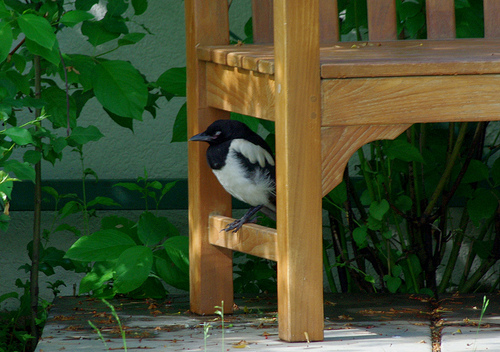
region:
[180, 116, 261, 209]
this is a bird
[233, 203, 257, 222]
this is the leg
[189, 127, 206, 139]
this is the beak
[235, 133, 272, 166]
this is the wing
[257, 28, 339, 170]
this is a bench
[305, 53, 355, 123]
the bench is brown in color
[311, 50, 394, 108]
the bench is wooden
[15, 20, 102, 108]
this is a tree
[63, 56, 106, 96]
the leaves are green in color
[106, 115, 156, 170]
this is a wall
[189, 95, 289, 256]
black and white bird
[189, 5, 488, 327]
light colored wooden bench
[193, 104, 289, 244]
bird standing on bottom of the bench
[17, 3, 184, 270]
buiding painted light green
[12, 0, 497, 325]
green plants growin near bench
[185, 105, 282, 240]
bird with a black beak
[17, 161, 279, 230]
green stripe along bottom of building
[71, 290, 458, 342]
shadows on ground below bench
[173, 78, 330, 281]
only one bird on the bench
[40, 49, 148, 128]
bright green leaves on plant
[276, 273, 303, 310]
edge of a stand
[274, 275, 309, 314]
part of a stand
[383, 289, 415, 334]
part of a shade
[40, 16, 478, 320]
A bird resting underneath a bench.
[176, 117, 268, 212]
this is a bird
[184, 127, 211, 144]
the beak is black in color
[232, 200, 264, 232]
this is the leg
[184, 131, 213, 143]
the beak is short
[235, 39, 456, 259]
this is the bench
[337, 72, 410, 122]
the bench is wooden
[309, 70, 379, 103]
the bench is brown in color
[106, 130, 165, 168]
this is the wall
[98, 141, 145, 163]
the wall is white in color